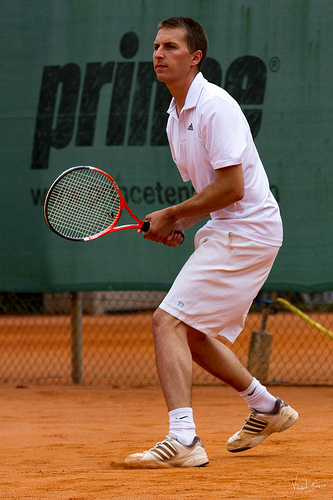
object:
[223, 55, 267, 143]
letter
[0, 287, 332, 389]
chain link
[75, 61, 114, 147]
letter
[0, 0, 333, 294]
sign